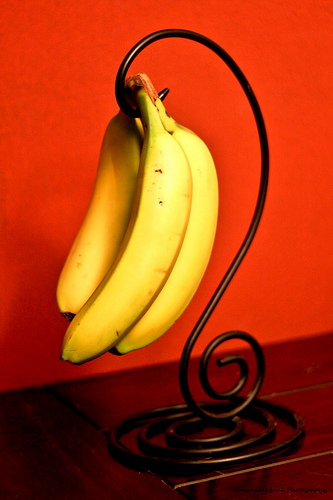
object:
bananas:
[105, 89, 218, 367]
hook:
[107, 28, 171, 118]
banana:
[59, 75, 193, 366]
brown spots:
[154, 168, 163, 175]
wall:
[1, 0, 331, 395]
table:
[1, 332, 332, 500]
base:
[109, 396, 306, 471]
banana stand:
[107, 29, 305, 469]